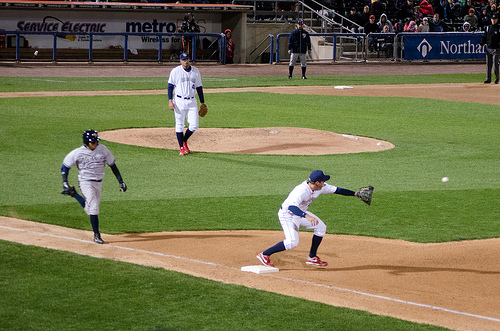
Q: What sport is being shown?
A: Baseball.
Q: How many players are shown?
A: Three.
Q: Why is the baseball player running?
A: To get to base.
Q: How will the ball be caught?
A: With a mit.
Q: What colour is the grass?
A: Green.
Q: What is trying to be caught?
A: A baseball.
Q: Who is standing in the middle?
A: The pitcher.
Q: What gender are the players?
A: Male.